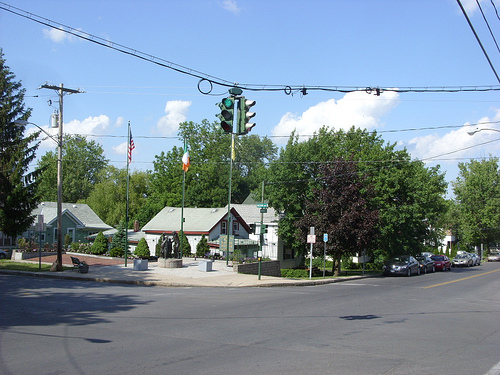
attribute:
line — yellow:
[406, 261, 491, 306]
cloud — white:
[400, 108, 499, 193]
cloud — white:
[270, 85, 400, 141]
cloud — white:
[160, 98, 192, 135]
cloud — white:
[24, 112, 130, 163]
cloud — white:
[44, 24, 111, 45]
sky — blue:
[1, 0, 499, 200]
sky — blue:
[226, 14, 488, 148]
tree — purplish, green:
[303, 157, 384, 281]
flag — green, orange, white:
[181, 136, 192, 178]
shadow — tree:
[1, 272, 154, 329]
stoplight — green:
[218, 86, 255, 136]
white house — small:
[140, 169, 269, 267]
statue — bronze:
[156, 235, 179, 253]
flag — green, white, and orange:
[174, 135, 195, 175]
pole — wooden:
[30, 65, 95, 276]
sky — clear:
[203, 7, 449, 72]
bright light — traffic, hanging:
[215, 85, 257, 142]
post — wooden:
[20, 72, 86, 269]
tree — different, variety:
[290, 127, 390, 277]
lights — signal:
[215, 87, 256, 135]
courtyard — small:
[24, 251, 288, 290]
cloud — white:
[272, 84, 400, 149]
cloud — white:
[412, 112, 498, 202]